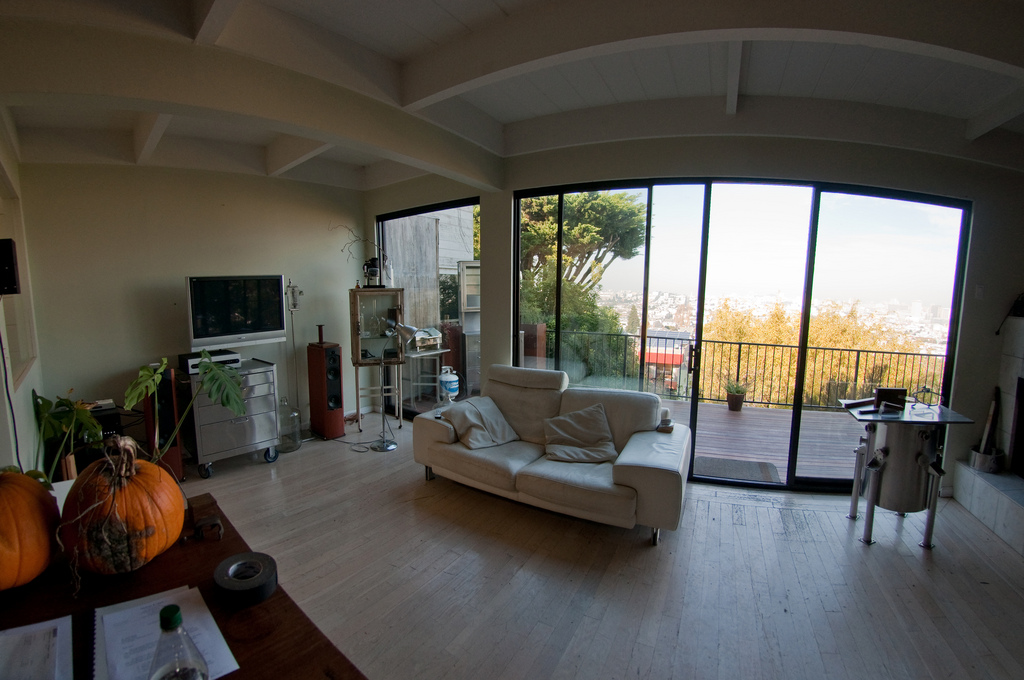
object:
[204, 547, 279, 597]
tape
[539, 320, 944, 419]
railing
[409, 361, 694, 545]
loveseat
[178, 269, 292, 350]
flatscreentelevision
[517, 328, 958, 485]
balcony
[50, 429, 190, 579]
pumpkin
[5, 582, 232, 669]
paperwork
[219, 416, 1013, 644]
light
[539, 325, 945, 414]
rail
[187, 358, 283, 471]
cabinet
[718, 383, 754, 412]
plant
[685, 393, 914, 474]
floor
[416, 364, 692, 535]
couch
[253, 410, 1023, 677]
floor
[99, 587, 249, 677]
papers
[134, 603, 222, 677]
bottle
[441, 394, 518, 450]
pillow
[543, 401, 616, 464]
pillow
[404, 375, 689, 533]
sofa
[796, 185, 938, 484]
window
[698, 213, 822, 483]
window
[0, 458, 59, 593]
pumpkin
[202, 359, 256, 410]
leaf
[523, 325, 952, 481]
deck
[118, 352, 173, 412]
leaves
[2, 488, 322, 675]
counter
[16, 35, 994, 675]
living room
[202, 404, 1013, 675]
flooring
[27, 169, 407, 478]
wall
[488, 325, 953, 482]
patio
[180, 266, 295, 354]
television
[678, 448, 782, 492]
floor mat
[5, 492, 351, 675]
table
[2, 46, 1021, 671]
room